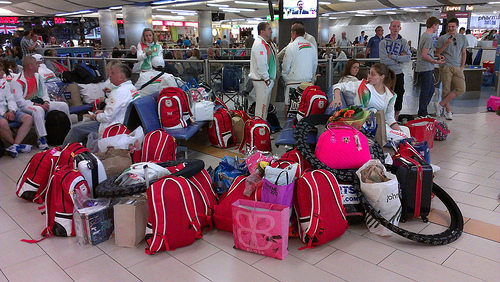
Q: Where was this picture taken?
A: Airport.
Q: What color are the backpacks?
A: Red.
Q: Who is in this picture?
A: People.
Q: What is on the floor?
A: Luggage.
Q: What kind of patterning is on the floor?
A: Tile.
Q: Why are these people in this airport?
A: Travel.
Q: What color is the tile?
A: White.